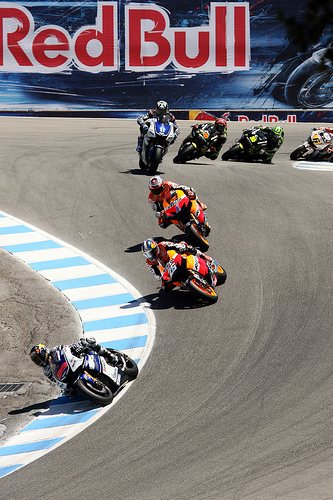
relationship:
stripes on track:
[1, 209, 157, 479] [2, 115, 331, 499]